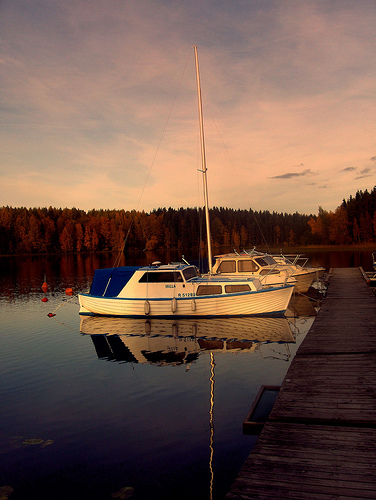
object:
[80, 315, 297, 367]
reflection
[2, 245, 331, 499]
water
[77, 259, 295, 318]
boat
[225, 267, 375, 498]
dock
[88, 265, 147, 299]
tarp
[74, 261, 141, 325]
end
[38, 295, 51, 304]
buoy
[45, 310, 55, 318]
buoy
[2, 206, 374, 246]
foliage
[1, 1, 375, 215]
sky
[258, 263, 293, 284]
equipment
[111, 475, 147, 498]
fishing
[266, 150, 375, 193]
clouds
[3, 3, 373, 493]
area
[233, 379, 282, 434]
debris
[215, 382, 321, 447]
bottom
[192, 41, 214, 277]
mast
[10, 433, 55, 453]
pads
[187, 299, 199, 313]
float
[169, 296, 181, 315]
float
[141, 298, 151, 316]
float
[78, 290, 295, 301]
blue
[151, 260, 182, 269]
accessory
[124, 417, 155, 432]
fish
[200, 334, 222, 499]
reflection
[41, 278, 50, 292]
buoy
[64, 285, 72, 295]
buoy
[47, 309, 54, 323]
buoy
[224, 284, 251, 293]
window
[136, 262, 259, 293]
cabin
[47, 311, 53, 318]
buoy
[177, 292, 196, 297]
number